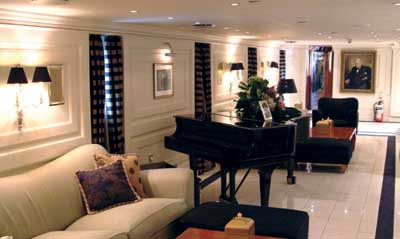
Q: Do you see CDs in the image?
A: No, there are no cds.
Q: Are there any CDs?
A: No, there are no cds.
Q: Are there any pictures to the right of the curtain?
A: Yes, there is a picture to the right of the curtain.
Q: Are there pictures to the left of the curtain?
A: No, the picture is to the right of the curtain.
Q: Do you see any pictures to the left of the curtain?
A: No, the picture is to the right of the curtain.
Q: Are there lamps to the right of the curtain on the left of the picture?
A: No, there is a picture to the right of the curtain.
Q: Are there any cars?
A: No, there are no cars.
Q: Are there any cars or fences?
A: No, there are no cars or fences.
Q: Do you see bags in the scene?
A: No, there are no bags.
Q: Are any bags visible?
A: No, there are no bags.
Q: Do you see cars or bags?
A: No, there are no bags or cars.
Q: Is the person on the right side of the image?
A: Yes, the person is on the right of the image.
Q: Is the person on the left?
A: No, the person is on the right of the image.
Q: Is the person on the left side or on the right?
A: The person is on the right of the image.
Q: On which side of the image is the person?
A: The person is on the right of the image.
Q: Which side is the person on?
A: The person is on the right of the image.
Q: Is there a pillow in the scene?
A: Yes, there is a pillow.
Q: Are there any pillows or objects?
A: Yes, there is a pillow.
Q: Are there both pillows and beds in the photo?
A: No, there is a pillow but no beds.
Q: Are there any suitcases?
A: No, there are no suitcases.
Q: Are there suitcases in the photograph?
A: No, there are no suitcases.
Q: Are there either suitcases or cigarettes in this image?
A: No, there are no suitcases or cigarettes.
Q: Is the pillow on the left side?
A: Yes, the pillow is on the left of the image.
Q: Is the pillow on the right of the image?
A: No, the pillow is on the left of the image.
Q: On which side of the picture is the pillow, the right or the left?
A: The pillow is on the left of the image.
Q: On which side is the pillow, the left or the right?
A: The pillow is on the left of the image.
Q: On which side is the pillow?
A: The pillow is on the left of the image.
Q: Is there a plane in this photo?
A: No, there are no airplanes.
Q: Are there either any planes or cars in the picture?
A: No, there are no planes or cars.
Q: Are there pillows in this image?
A: Yes, there are pillows.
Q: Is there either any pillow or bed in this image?
A: Yes, there are pillows.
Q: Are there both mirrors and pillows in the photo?
A: No, there are pillows but no mirrors.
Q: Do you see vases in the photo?
A: No, there are no vases.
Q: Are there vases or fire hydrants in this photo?
A: No, there are no vases or fire hydrants.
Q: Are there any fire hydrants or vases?
A: No, there are no vases or fire hydrants.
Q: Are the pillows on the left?
A: Yes, the pillows are on the left of the image.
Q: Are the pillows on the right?
A: No, the pillows are on the left of the image.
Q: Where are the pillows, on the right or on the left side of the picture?
A: The pillows are on the left of the image.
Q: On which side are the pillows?
A: The pillows are on the left of the image.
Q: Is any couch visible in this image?
A: Yes, there is a couch.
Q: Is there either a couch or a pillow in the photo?
A: Yes, there is a couch.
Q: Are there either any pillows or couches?
A: Yes, there is a couch.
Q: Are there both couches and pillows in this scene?
A: Yes, there are both a couch and a pillow.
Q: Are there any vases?
A: No, there are no vases.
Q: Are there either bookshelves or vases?
A: No, there are no vases or bookshelves.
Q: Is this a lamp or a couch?
A: This is a couch.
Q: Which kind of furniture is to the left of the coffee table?
A: The piece of furniture is a couch.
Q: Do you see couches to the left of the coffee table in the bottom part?
A: Yes, there is a couch to the left of the coffee table.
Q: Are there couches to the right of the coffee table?
A: No, the couch is to the left of the coffee table.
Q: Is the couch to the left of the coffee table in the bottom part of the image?
A: Yes, the couch is to the left of the coffee table.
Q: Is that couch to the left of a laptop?
A: No, the couch is to the left of the coffee table.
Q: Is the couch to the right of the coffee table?
A: No, the couch is to the left of the coffee table.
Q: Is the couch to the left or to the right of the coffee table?
A: The couch is to the left of the coffee table.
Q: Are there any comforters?
A: No, there are no comforters.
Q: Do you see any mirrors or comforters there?
A: No, there are no comforters or mirrors.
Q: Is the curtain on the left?
A: Yes, the curtain is on the left of the image.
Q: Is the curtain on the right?
A: No, the curtain is on the left of the image.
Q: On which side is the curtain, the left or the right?
A: The curtain is on the left of the image.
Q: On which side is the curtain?
A: The curtain is on the left of the image.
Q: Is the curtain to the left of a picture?
A: Yes, the curtain is to the left of a picture.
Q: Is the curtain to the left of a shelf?
A: No, the curtain is to the left of a picture.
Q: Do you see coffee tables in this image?
A: Yes, there is a coffee table.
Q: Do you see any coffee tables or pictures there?
A: Yes, there is a coffee table.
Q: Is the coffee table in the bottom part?
A: Yes, the coffee table is in the bottom of the image.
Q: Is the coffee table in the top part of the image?
A: No, the coffee table is in the bottom of the image.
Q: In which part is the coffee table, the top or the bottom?
A: The coffee table is in the bottom of the image.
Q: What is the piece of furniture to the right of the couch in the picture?
A: The piece of furniture is a coffee table.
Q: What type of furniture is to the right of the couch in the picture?
A: The piece of furniture is a coffee table.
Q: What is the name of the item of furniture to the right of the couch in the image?
A: The piece of furniture is a coffee table.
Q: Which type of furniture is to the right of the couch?
A: The piece of furniture is a coffee table.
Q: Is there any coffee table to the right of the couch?
A: Yes, there is a coffee table to the right of the couch.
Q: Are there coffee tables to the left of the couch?
A: No, the coffee table is to the right of the couch.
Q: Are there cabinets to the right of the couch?
A: No, there is a coffee table to the right of the couch.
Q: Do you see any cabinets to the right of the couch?
A: No, there is a coffee table to the right of the couch.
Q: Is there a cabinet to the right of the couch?
A: No, there is a coffee table to the right of the couch.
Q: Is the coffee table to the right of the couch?
A: Yes, the coffee table is to the right of the couch.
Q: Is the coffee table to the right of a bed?
A: No, the coffee table is to the right of the couch.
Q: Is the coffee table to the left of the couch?
A: No, the coffee table is to the right of the couch.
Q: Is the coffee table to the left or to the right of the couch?
A: The coffee table is to the right of the couch.